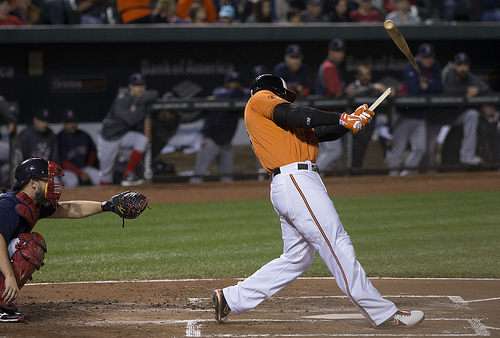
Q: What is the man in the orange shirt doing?
A: Swinging a bat.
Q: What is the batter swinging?
A: A bat.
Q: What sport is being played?
A: Baseball.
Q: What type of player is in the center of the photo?
A: The Batter.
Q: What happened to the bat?
A: It broke into two pieces.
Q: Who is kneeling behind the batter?
A: The catcher.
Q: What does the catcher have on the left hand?
A: A Baseball mit.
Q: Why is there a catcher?
A: To catch any balls that the batter doesn't hit.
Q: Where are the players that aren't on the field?
A: In the dugout.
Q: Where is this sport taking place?
A: In a baseball stadium.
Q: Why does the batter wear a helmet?
A: To protect his head from being hit by a ball.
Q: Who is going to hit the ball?
A: A baseball player wearing an orange shirt.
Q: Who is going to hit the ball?
A: A baseball player wearing white pants.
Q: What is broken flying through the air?
A: A bat.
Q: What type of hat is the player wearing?
A: A black hat.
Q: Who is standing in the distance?
A: The baseball players watching the game.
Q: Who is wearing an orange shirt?
A: The batter.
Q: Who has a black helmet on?
A: The batter.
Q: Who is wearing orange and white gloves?
A: The batter.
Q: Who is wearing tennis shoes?
A: The batter.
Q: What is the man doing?
A: Playing baseball.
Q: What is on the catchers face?
A: A mask.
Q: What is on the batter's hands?
A: Batting gloves.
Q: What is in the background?
A: Other players.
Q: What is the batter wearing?
A: A baseball uniform.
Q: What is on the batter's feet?
A: Cleats.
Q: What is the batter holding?
A: A broken bat.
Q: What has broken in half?
A: A baseball bat.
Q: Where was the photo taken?
A: At a baseball game.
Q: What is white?
A: Player's pants.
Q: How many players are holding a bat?
A: One.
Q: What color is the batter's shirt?
A: Yellow.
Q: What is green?
A: The grass.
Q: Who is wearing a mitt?
A: Catcher.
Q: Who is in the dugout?
A: Players.